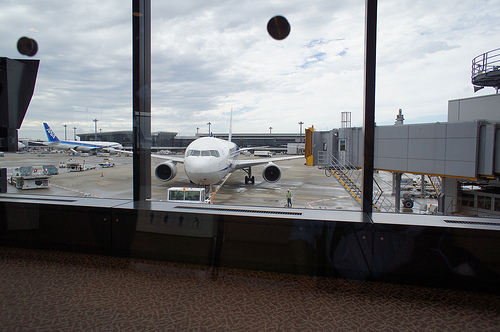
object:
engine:
[262, 163, 283, 183]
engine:
[154, 161, 178, 182]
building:
[194, 132, 305, 148]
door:
[313, 131, 333, 165]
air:
[0, 0, 479, 119]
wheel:
[252, 176, 255, 184]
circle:
[267, 15, 291, 40]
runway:
[28, 144, 187, 195]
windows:
[201, 150, 211, 156]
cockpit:
[183, 137, 228, 168]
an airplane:
[121, 135, 281, 186]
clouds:
[11, 0, 462, 108]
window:
[142, 0, 370, 210]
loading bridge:
[306, 122, 498, 181]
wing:
[108, 147, 184, 162]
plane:
[37, 122, 123, 155]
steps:
[332, 173, 343, 175]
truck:
[98, 161, 115, 168]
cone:
[100, 172, 103, 176]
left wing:
[236, 155, 304, 168]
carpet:
[0, 254, 497, 329]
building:
[75, 130, 138, 151]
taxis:
[165, 187, 208, 204]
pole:
[127, 0, 153, 199]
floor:
[18, 247, 483, 327]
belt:
[305, 126, 314, 164]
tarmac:
[12, 147, 392, 207]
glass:
[149, 0, 361, 206]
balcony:
[469, 49, 498, 88]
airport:
[0, 127, 435, 210]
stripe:
[52, 140, 104, 148]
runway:
[225, 154, 362, 203]